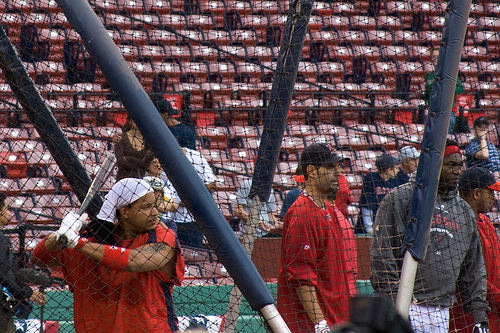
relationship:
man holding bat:
[33, 176, 183, 326] [55, 146, 116, 250]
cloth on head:
[92, 176, 153, 222] [111, 178, 156, 235]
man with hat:
[271, 111, 393, 306] [150, 97, 182, 118]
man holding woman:
[271, 111, 393, 306] [105, 104, 165, 186]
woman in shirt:
[105, 104, 165, 186] [109, 130, 157, 186]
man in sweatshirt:
[368, 132, 487, 321] [369, 175, 486, 312]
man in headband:
[368, 132, 487, 321] [445, 146, 458, 153]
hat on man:
[295, 124, 347, 172] [276, 140, 359, 331]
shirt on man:
[274, 184, 359, 324] [276, 140, 359, 331]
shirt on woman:
[112, 132, 155, 179] [111, 107, 153, 177]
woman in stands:
[111, 107, 153, 177] [1, 1, 498, 283]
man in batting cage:
[33, 176, 183, 326] [1, 0, 496, 331]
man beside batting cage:
[374, 134, 488, 332] [1, 0, 496, 331]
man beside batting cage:
[276, 140, 359, 331] [1, 0, 496, 331]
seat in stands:
[0, 147, 30, 177] [0, 3, 495, 238]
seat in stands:
[202, 54, 237, 81] [0, 3, 495, 238]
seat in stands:
[293, 55, 320, 78] [0, 3, 495, 238]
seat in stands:
[321, 37, 355, 59] [0, 3, 495, 238]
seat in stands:
[379, 40, 411, 59] [0, 3, 495, 238]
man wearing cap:
[457, 168, 497, 331] [419, 112, 499, 230]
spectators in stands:
[357, 152, 404, 236] [1, 1, 498, 283]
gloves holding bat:
[49, 208, 118, 279] [55, 146, 116, 250]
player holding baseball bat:
[26, 148, 189, 330] [50, 148, 121, 250]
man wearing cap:
[289, 138, 353, 218] [296, 141, 354, 173]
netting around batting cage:
[1, 0, 498, 330] [1, 0, 496, 331]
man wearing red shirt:
[23, 146, 190, 331] [33, 224, 186, 330]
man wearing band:
[374, 134, 488, 332] [443, 135, 465, 301]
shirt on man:
[275, 196, 380, 306] [276, 140, 359, 331]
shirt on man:
[31, 222, 189, 331] [33, 176, 183, 326]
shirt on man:
[450, 214, 499, 327] [450, 164, 496, 329]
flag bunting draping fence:
[179, 305, 226, 327] [0, 0, 446, 325]